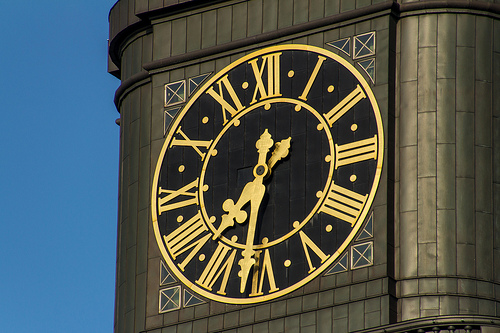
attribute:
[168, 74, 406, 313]
background — black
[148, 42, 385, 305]
clock — black, gold, beautiful, golden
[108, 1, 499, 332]
tower — grey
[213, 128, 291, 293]
hands — gold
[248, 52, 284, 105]
roman numerals — twelve, 12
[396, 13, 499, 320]
bricks — verticle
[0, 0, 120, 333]
sky — blue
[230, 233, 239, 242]
circle — gold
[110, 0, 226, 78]
shadows — cast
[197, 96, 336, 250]
circle — gold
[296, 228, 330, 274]
roman numerals — five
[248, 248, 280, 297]
number — 6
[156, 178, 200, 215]
number — 9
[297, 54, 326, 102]
number — 1, gold, roman numeral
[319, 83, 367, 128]
number — 2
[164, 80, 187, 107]
square — black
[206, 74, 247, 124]
object — roman numeral, roman number